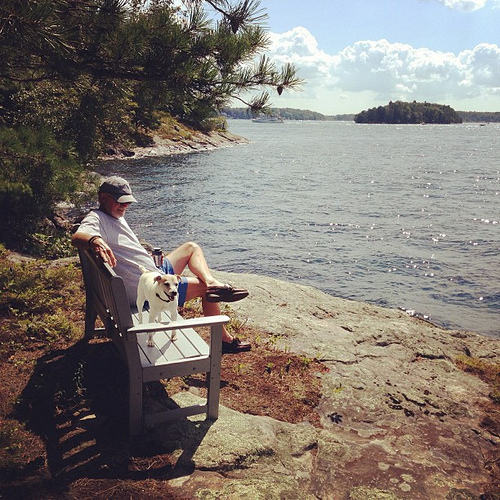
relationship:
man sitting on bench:
[70, 175, 253, 354] [70, 239, 229, 435]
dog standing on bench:
[135, 262, 184, 346] [70, 239, 229, 435]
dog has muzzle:
[135, 262, 184, 346] [165, 286, 179, 301]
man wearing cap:
[70, 175, 253, 354] [99, 176, 137, 207]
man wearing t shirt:
[70, 175, 253, 354] [76, 209, 165, 307]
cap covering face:
[99, 176, 137, 207] [115, 203, 129, 217]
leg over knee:
[168, 241, 249, 304] [198, 281, 207, 298]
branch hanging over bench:
[1, 1, 308, 141] [70, 239, 229, 435]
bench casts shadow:
[70, 239, 229, 435] [12, 339, 216, 483]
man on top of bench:
[70, 175, 253, 354] [70, 239, 229, 435]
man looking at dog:
[70, 175, 253, 354] [135, 262, 184, 346]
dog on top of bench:
[135, 262, 184, 346] [70, 239, 229, 435]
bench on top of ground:
[70, 239, 229, 435] [0, 244, 499, 499]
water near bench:
[79, 119, 500, 339] [70, 239, 229, 435]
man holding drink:
[70, 175, 253, 354] [152, 246, 164, 262]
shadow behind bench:
[12, 339, 216, 483] [70, 239, 229, 435]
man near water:
[70, 175, 253, 354] [79, 119, 500, 339]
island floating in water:
[354, 99, 463, 124] [79, 119, 500, 339]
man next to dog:
[70, 175, 253, 354] [135, 262, 184, 346]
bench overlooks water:
[70, 239, 229, 435] [79, 119, 500, 339]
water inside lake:
[79, 119, 500, 339] [68, 117, 500, 341]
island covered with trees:
[354, 99, 463, 124] [356, 99, 465, 124]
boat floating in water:
[251, 113, 285, 125] [79, 119, 500, 339]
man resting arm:
[70, 175, 253, 354] [70, 211, 117, 262]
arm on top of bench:
[70, 211, 117, 262] [70, 239, 229, 435]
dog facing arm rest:
[135, 262, 184, 346] [125, 313, 232, 331]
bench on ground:
[70, 239, 229, 435] [0, 244, 499, 499]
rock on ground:
[148, 391, 318, 470] [0, 244, 499, 499]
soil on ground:
[156, 304, 326, 421] [0, 244, 499, 499]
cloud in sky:
[238, 25, 500, 102] [122, 1, 500, 116]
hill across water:
[221, 107, 358, 121] [79, 119, 500, 339]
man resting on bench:
[70, 175, 253, 354] [70, 239, 229, 435]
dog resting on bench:
[135, 262, 184, 346] [70, 239, 229, 435]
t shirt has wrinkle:
[76, 209, 165, 307] [107, 240, 151, 258]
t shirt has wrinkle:
[76, 209, 165, 307] [112, 219, 138, 242]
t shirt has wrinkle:
[76, 209, 165, 307] [113, 251, 145, 272]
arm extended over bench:
[70, 211, 117, 262] [70, 239, 229, 435]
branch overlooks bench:
[1, 1, 308, 141] [70, 239, 229, 435]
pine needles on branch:
[247, 14, 268, 23] [1, 1, 308, 141]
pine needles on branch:
[255, 92, 272, 106] [1, 1, 308, 141]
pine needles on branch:
[281, 60, 308, 83] [1, 1, 308, 141]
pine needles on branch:
[189, 6, 218, 33] [1, 1, 308, 141]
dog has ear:
[135, 262, 184, 346] [154, 274, 164, 282]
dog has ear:
[135, 262, 184, 346] [176, 274, 182, 282]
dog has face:
[135, 262, 184, 346] [154, 274, 183, 301]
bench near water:
[70, 239, 229, 435] [79, 119, 500, 339]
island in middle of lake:
[354, 99, 463, 124] [68, 117, 500, 341]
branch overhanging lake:
[1, 1, 308, 141] [68, 117, 500, 341]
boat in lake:
[251, 113, 285, 125] [68, 117, 500, 341]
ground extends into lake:
[0, 244, 499, 499] [68, 117, 500, 341]